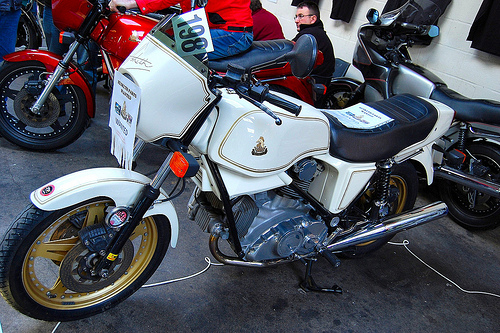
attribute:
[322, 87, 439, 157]
seat — black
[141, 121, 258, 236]
bars — black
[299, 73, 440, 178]
seat — black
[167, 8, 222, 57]
label — printed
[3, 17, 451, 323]
bike — white, black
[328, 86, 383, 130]
paper — white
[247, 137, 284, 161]
logo — gold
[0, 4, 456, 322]
motorcycle — white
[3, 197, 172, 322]
wheel — black, gold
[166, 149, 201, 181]
signal — red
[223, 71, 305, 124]
handlebar — black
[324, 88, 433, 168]
seat — black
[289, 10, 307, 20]
glasses — framed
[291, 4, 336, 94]
man — bad sentence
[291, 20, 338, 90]
jacket — black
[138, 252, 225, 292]
cord — white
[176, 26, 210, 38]
9 — black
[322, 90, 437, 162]
seat — black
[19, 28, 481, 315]
motorbike — red, shiny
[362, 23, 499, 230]
bike — grey, white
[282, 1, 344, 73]
man — in black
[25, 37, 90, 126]
fender — red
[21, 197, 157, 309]
wheel — gold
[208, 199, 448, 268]
exhaust pipe — chrome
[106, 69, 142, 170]
sign — white